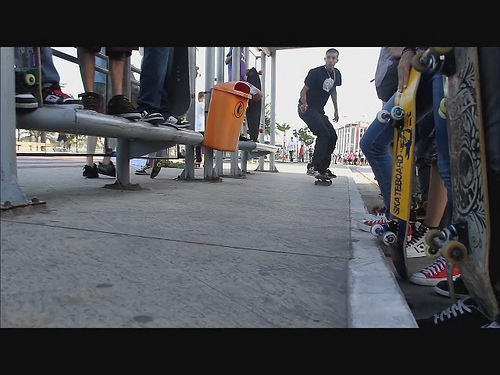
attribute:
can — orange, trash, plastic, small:
[206, 79, 255, 155]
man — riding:
[298, 48, 344, 179]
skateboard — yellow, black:
[370, 64, 428, 288]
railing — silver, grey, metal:
[1, 46, 286, 209]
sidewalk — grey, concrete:
[5, 164, 349, 328]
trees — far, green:
[277, 120, 317, 168]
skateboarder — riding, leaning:
[297, 46, 346, 180]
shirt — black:
[296, 66, 345, 112]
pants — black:
[293, 101, 339, 174]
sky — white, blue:
[52, 47, 383, 129]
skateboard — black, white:
[410, 48, 500, 314]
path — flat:
[7, 155, 347, 308]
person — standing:
[71, 42, 145, 120]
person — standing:
[137, 45, 187, 128]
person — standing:
[12, 41, 87, 117]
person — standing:
[365, 47, 447, 234]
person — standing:
[416, 47, 500, 331]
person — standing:
[407, 45, 474, 290]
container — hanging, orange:
[205, 72, 253, 151]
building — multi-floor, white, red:
[335, 114, 376, 165]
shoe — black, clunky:
[105, 92, 144, 120]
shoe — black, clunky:
[75, 91, 102, 117]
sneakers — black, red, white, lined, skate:
[361, 213, 480, 322]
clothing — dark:
[300, 66, 344, 172]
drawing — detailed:
[449, 48, 478, 291]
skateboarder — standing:
[394, 48, 476, 287]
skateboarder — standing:
[357, 48, 431, 240]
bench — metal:
[3, 46, 286, 209]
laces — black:
[110, 94, 134, 110]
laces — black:
[75, 91, 101, 104]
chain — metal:
[324, 66, 340, 82]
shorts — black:
[73, 48, 134, 61]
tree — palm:
[276, 121, 290, 162]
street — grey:
[351, 161, 385, 211]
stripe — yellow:
[353, 164, 382, 202]